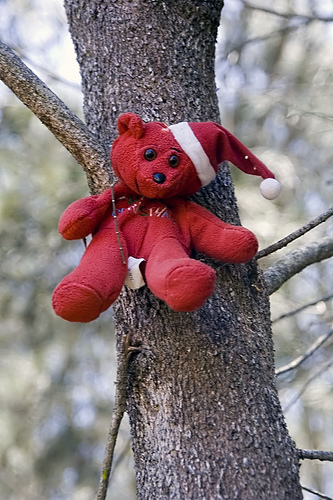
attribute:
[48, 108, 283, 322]
bear — red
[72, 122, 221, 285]
toy — christmas themed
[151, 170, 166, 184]
nose — button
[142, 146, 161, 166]
eye — black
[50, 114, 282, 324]
teddy bear — red, dark red, christmas themed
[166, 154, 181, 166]
eye — button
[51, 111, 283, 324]
toy — red, fuzzy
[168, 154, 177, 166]
eye — black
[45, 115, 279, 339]
doll — red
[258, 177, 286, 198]
puff — round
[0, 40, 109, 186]
branch — rough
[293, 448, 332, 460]
branch — rough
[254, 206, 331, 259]
branch — rough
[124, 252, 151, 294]
tag — white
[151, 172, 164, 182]
nose — black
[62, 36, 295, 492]
bark — rough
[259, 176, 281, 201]
ball — white